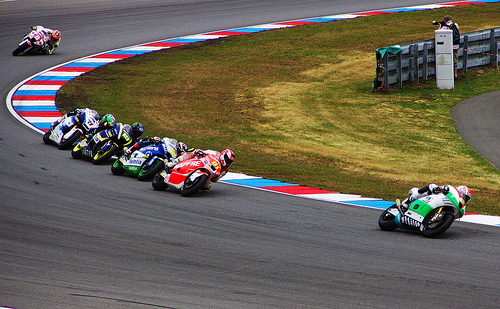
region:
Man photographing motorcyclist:
[427, 13, 462, 83]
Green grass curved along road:
[52, 0, 497, 225]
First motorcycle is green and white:
[370, 175, 473, 234]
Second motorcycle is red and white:
[152, 145, 233, 198]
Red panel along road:
[10, 90, 54, 102]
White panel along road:
[18, 82, 63, 89]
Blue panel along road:
[11, 86, 61, 97]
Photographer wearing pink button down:
[430, 11, 460, 83]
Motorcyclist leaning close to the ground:
[1, 20, 65, 62]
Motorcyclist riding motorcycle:
[377, 171, 472, 240]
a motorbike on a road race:
[368, 170, 483, 249]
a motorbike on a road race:
[151, 145, 241, 190]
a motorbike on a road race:
[111, 131, 185, 181]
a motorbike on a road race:
[76, 122, 146, 162]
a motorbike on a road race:
[34, 100, 101, 147]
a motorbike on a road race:
[7, 23, 66, 65]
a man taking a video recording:
[431, 11, 471, 86]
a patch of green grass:
[46, 0, 491, 183]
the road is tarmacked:
[0, 2, 497, 307]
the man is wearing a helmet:
[221, 143, 236, 171]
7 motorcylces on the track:
[26, 11, 482, 283]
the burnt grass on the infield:
[195, 64, 367, 201]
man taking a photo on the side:
[414, 8, 467, 47]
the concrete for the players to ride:
[81, 237, 223, 284]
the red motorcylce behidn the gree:
[162, 148, 250, 196]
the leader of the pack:
[410, 154, 442, 229]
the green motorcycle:
[349, 165, 485, 256]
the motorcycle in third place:
[126, 134, 165, 174]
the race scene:
[4, 12, 482, 305]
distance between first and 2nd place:
[244, 180, 378, 239]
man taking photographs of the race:
[423, 8, 470, 93]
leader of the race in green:
[369, 160, 473, 247]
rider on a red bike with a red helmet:
[155, 134, 233, 197]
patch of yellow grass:
[263, 72, 388, 166]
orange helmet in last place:
[2, 10, 70, 63]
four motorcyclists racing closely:
[37, 90, 233, 200]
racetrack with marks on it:
[27, 197, 272, 283]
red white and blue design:
[2, 68, 61, 116]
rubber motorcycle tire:
[8, 37, 35, 57]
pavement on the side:
[462, 103, 494, 152]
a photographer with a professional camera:
[430, 14, 460, 79]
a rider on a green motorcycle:
[375, 181, 473, 237]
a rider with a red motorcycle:
[150, 147, 235, 198]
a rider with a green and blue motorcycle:
[109, 136, 193, 182]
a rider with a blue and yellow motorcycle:
[67, 119, 146, 164]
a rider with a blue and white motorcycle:
[42, 107, 116, 152]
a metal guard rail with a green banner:
[368, 21, 498, 85]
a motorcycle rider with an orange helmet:
[11, 22, 63, 57]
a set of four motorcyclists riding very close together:
[40, 104, 237, 194]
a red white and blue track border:
[6, 0, 498, 227]